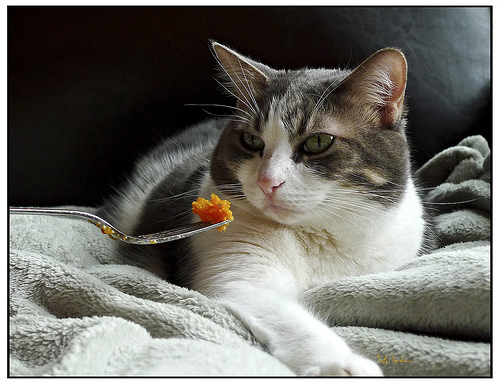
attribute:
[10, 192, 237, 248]
fork — metal, silver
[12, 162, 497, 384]
blanket — grey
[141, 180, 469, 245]
whiskers — white, long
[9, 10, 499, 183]
couch — leather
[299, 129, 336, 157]
eye — green, black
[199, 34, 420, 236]
face — furry 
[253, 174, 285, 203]
nose — pink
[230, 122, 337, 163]
eyes — green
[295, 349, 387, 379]
paw — white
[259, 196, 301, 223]
mouth — closed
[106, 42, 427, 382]
cat — furry, furred, white, brown, black, spoiled, soft